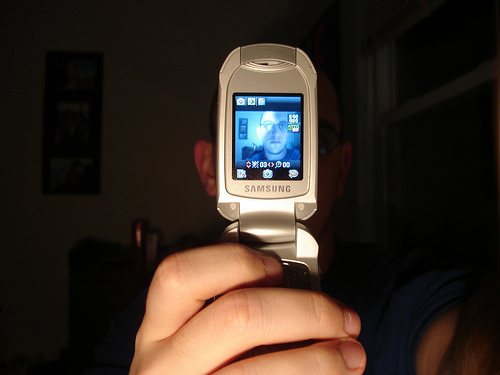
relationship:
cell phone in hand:
[215, 43, 319, 293] [120, 239, 373, 371]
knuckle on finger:
[151, 251, 211, 298] [140, 244, 287, 299]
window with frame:
[357, 0, 500, 245] [380, 41, 461, 158]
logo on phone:
[243, 174, 305, 201] [194, 33, 332, 319]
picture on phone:
[234, 107, 298, 169] [213, 45, 322, 289]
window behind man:
[408, 70, 489, 286] [195, 89, 363, 232]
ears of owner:
[197, 129, 224, 182] [179, 90, 353, 327]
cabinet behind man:
[84, 48, 382, 276] [201, 43, 400, 268]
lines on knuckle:
[234, 294, 267, 324] [218, 288, 273, 333]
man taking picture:
[99, 18, 392, 322] [183, 29, 336, 286]